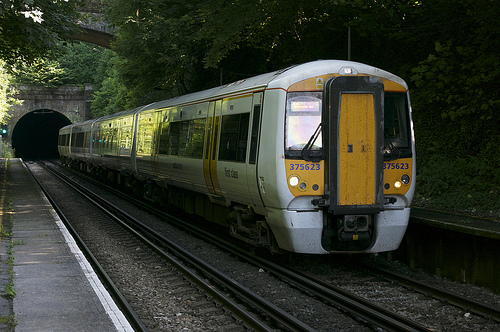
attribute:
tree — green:
[417, 44, 493, 157]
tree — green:
[86, 57, 139, 119]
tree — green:
[111, 24, 178, 95]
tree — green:
[193, 0, 313, 71]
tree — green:
[0, 1, 81, 84]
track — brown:
[21, 156, 355, 330]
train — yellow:
[78, 57, 386, 254]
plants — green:
[1, 19, 168, 80]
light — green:
[1, 125, 7, 139]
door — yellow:
[203, 99, 223, 204]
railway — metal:
[32, 138, 490, 329]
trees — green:
[83, 0, 498, 180]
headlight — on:
[290, 177, 304, 185]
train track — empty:
[123, 229, 235, 330]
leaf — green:
[62, 42, 68, 45]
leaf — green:
[71, 43, 75, 45]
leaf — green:
[8, 60, 13, 63]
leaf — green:
[39, 65, 44, 69]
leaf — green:
[28, 49, 33, 51]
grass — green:
[2, 178, 37, 329]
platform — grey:
[7, 150, 117, 330]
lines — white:
[18, 153, 117, 330]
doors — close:
[165, 107, 257, 207]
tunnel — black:
[9, 106, 83, 166]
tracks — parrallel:
[131, 210, 273, 315]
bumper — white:
[265, 207, 411, 254]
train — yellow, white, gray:
[55, 60, 416, 254]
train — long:
[41, 51, 417, 263]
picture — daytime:
[15, 15, 480, 322]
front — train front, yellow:
[283, 75, 413, 216]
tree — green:
[98, 15, 185, 95]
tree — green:
[420, 16, 483, 122]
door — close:
[197, 100, 213, 192]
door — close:
[213, 101, 222, 195]